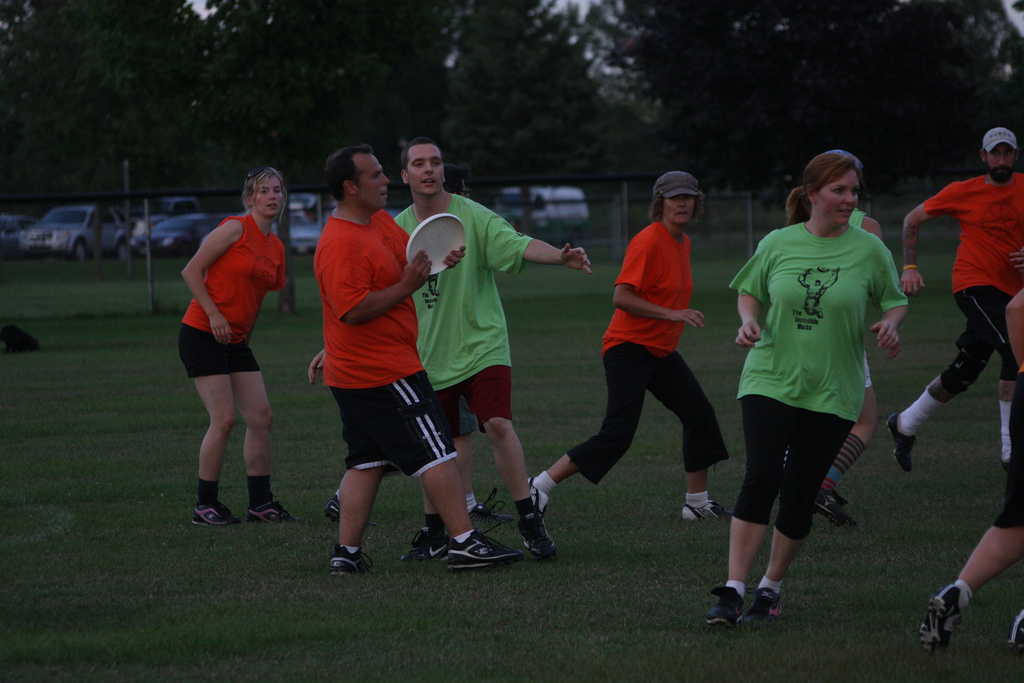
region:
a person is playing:
[172, 160, 303, 527]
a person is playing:
[299, 142, 530, 563]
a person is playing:
[389, 134, 590, 549]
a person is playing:
[517, 164, 734, 535]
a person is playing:
[705, 139, 906, 631]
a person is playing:
[897, 136, 1022, 484]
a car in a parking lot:
[27, 198, 138, 268]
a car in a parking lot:
[485, 166, 583, 230]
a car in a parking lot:
[263, 202, 324, 257]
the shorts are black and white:
[333, 369, 461, 474]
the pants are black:
[569, 343, 726, 479]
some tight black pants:
[743, 396, 852, 536]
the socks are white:
[719, 573, 783, 594]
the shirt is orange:
[181, 214, 284, 345]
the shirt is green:
[399, 195, 527, 386]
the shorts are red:
[433, 363, 511, 439]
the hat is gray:
[652, 172, 703, 198]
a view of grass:
[522, 613, 691, 680]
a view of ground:
[482, 538, 691, 647]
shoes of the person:
[640, 544, 857, 644]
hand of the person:
[533, 199, 607, 389]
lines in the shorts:
[343, 342, 500, 533]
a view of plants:
[483, 67, 870, 185]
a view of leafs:
[123, 42, 387, 147]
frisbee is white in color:
[388, 205, 507, 298]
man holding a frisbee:
[391, 217, 480, 290]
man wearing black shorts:
[309, 353, 464, 489]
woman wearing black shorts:
[173, 307, 266, 383]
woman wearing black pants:
[546, 334, 723, 502]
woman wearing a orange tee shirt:
[186, 215, 282, 349]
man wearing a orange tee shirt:
[923, 165, 1022, 324]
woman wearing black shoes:
[692, 562, 844, 629]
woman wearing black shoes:
[919, 579, 1022, 647]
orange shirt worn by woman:
[180, 200, 294, 352]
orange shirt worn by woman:
[614, 218, 707, 367]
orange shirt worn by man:
[317, 212, 410, 396]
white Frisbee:
[403, 204, 471, 278]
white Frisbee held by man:
[398, 206, 472, 314]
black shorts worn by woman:
[170, 320, 263, 384]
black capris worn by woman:
[742, 392, 842, 551]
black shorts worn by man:
[334, 367, 456, 467]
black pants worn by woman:
[595, 344, 723, 481]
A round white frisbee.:
[403, 211, 470, 275]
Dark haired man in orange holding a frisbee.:
[315, 142, 522, 573]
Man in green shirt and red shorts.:
[308, 141, 593, 560]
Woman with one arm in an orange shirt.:
[174, 166, 307, 525]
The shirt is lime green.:
[755, 238, 876, 410]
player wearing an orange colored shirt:
[299, 144, 514, 581]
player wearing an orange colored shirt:
[158, 150, 320, 536]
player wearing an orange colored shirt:
[531, 131, 737, 536]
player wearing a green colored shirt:
[687, 131, 932, 616]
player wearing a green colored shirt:
[367, 130, 606, 549]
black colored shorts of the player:
[297, 333, 469, 488]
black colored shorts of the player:
[174, 317, 267, 393]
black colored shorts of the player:
[549, 339, 726, 494]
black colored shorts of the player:
[702, 364, 879, 542]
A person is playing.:
[306, 136, 510, 579]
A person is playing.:
[364, 115, 571, 561]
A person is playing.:
[147, 140, 300, 520]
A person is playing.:
[550, 140, 734, 515]